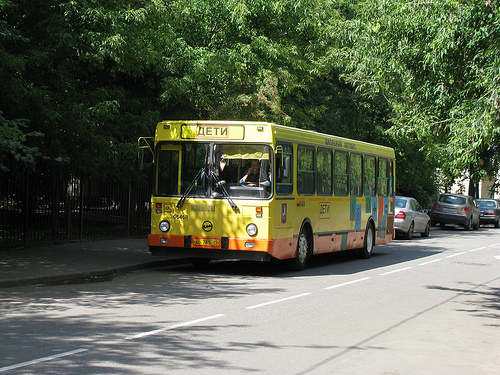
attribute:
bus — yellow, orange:
[136, 120, 396, 269]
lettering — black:
[197, 127, 227, 137]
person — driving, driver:
[240, 162, 270, 188]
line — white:
[126, 313, 225, 340]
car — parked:
[396, 195, 431, 238]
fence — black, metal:
[0, 169, 151, 247]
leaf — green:
[114, 100, 120, 107]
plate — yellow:
[191, 239, 220, 248]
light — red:
[395, 210, 406, 220]